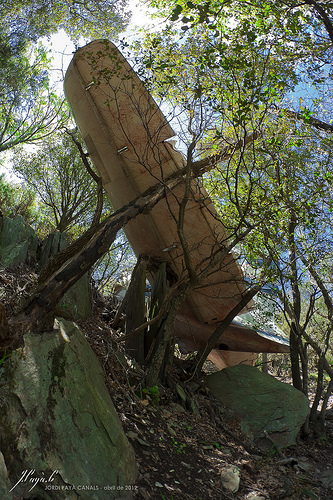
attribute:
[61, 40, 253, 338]
rock — large, a wing, wing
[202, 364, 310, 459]
leaves — green, large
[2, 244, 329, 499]
dirt — brown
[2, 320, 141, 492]
leaves — green, large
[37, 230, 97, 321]
leaves — green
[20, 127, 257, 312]
trunk — woodn, brown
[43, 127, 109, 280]
trunk — woodn, brown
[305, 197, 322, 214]
leaf — green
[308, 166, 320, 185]
leaf — green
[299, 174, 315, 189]
leaf — green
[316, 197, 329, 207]
leaf — green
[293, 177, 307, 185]
leaf — green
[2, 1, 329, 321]
sky — vblue, blue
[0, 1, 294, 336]
cloud — white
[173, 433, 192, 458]
leaf — dried, small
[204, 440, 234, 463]
leaf — dried, small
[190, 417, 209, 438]
leaf — dried, small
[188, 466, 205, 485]
leaf — dried, small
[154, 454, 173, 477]
leaf — dried, small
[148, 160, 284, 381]
trunk — woodn, brown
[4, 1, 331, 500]
picture — daytime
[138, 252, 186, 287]
weeds — green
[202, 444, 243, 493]
rock — gray, small